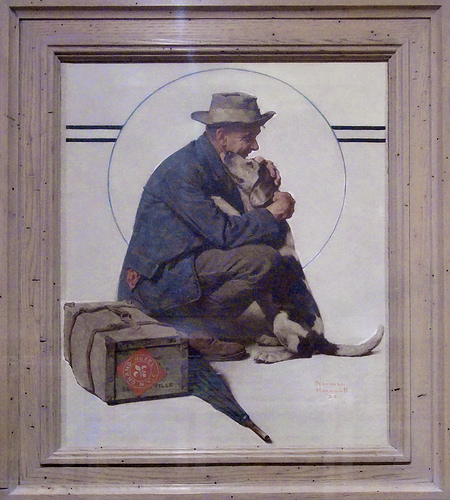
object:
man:
[117, 92, 282, 361]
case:
[64, 302, 190, 406]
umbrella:
[188, 344, 269, 442]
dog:
[210, 151, 384, 363]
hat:
[191, 93, 276, 126]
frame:
[1, 1, 448, 499]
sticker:
[117, 348, 167, 396]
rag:
[127, 269, 140, 290]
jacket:
[117, 137, 281, 314]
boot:
[191, 330, 246, 361]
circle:
[108, 67, 346, 268]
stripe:
[65, 125, 121, 130]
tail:
[321, 325, 385, 356]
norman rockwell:
[61, 61, 392, 449]